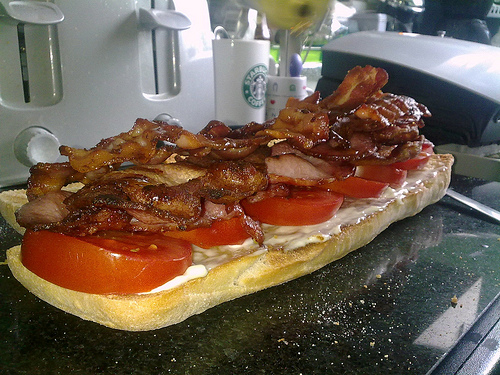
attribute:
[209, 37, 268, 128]
coffee mug — Starbuck's 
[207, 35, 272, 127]
mug — white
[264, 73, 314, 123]
coffee cup — small, white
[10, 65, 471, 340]
sandwich — large, open-faced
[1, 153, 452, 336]
bread — Italian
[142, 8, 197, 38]
lever — white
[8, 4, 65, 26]
lever — white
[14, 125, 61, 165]
knob — round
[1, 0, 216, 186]
toaster — white  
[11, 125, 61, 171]
knob — white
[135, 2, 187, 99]
toaster lever — white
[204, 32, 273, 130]
mug — White , Starbucks  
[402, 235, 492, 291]
counter — Black 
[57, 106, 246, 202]
bacon — crunchy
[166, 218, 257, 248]
tomato — sliced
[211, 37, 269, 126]
mug — white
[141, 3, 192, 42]
handle — White 